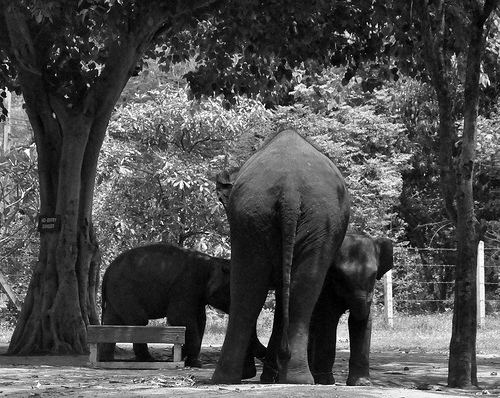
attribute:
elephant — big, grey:
[213, 128, 349, 386]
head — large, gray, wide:
[342, 235, 381, 307]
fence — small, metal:
[390, 224, 494, 319]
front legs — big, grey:
[171, 307, 215, 379]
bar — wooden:
[81, 323, 193, 365]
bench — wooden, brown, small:
[80, 319, 196, 389]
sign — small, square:
[32, 210, 64, 235]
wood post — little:
[76, 317, 201, 367]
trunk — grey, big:
[348, 286, 373, 323]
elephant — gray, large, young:
[286, 224, 393, 394]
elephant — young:
[308, 225, 402, 392]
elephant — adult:
[219, 124, 356, 385]